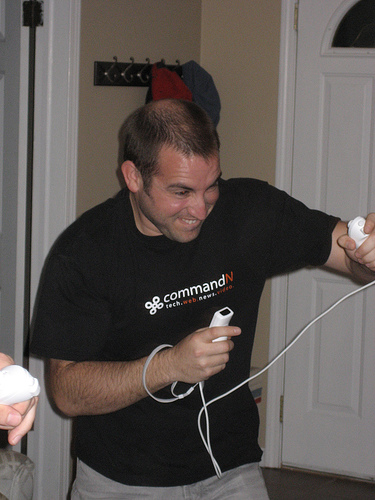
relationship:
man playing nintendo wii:
[22, 98, 375, 500] [202, 301, 233, 373]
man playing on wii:
[22, 98, 375, 500] [350, 218, 365, 243]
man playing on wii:
[22, 98, 375, 500] [213, 307, 232, 325]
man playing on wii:
[112, 151, 335, 363] [345, 222, 366, 243]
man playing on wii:
[22, 98, 375, 500] [194, 214, 367, 478]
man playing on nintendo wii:
[22, 98, 375, 500] [147, 214, 374, 477]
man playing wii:
[22, 98, 375, 500] [141, 215, 363, 474]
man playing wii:
[22, 98, 375, 500] [174, 219, 371, 432]